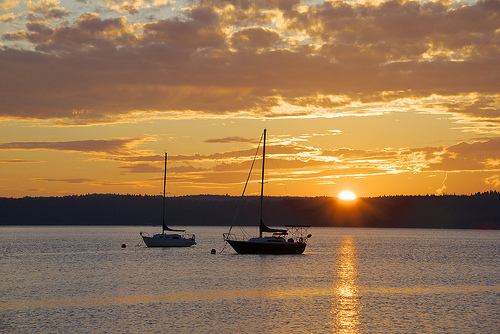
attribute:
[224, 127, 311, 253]
sailboat — large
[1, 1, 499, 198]
sunset — bright orange, line, blue, setting, orange, beautiful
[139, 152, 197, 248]
sailboat — small, anchored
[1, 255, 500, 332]
water — calm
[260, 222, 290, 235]
sails — down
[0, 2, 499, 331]
sunrise — cloudy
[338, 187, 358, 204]
sun — setting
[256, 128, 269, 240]
sailboat mast — tall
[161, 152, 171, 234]
mast — shorter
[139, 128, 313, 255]
boats — tiny, sailing, drifting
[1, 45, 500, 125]
cloud — thick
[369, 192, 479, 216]
hill — black